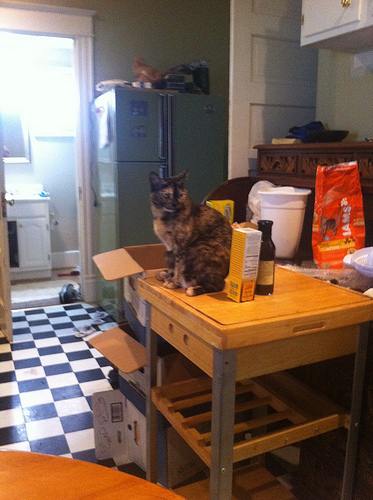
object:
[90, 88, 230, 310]
fridge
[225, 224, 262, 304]
box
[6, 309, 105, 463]
floor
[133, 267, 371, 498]
cart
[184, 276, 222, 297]
tail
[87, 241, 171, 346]
boxes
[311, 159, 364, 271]
bag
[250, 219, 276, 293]
bottle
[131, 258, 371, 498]
table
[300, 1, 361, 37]
door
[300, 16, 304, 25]
knob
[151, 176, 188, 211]
face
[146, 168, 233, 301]
cat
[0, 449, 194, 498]
table